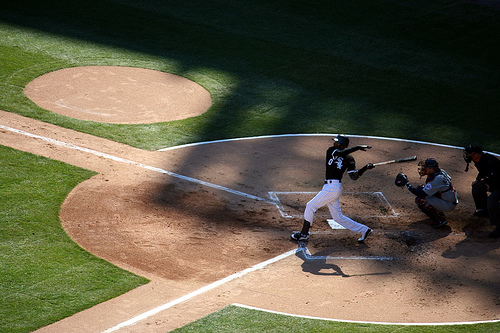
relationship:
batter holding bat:
[296, 129, 364, 243] [366, 151, 421, 175]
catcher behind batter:
[395, 147, 465, 239] [296, 129, 364, 243]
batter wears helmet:
[296, 129, 364, 243] [317, 128, 369, 155]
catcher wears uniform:
[395, 147, 465, 239] [418, 176, 454, 205]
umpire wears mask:
[454, 140, 497, 222] [401, 145, 483, 181]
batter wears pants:
[296, 129, 364, 243] [288, 174, 378, 235]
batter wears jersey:
[296, 129, 364, 243] [303, 144, 373, 188]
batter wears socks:
[296, 129, 364, 243] [296, 217, 320, 234]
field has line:
[233, 65, 378, 137] [117, 144, 256, 203]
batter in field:
[296, 129, 364, 243] [233, 65, 378, 137]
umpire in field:
[454, 140, 497, 222] [233, 65, 378, 137]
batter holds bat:
[296, 129, 364, 243] [366, 151, 421, 175]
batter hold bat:
[296, 129, 364, 243] [366, 151, 421, 175]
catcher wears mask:
[395, 147, 465, 239] [401, 145, 483, 181]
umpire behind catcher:
[454, 140, 497, 222] [395, 147, 465, 239]